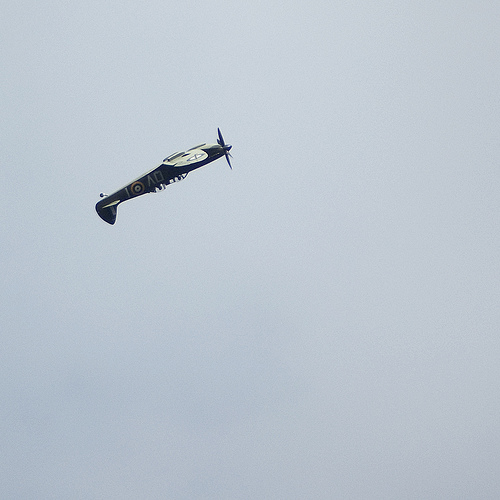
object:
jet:
[95, 126, 234, 225]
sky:
[2, 0, 500, 499]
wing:
[163, 149, 209, 167]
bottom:
[163, 149, 208, 167]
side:
[121, 164, 180, 201]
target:
[131, 182, 145, 196]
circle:
[135, 185, 140, 192]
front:
[215, 142, 232, 158]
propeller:
[216, 128, 233, 170]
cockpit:
[144, 172, 188, 193]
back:
[94, 192, 120, 225]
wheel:
[100, 193, 104, 198]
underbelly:
[126, 142, 220, 186]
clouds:
[0, 0, 499, 499]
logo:
[186, 154, 204, 161]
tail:
[95, 197, 121, 225]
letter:
[148, 175, 157, 187]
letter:
[154, 170, 164, 183]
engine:
[224, 143, 231, 152]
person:
[156, 184, 162, 190]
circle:
[130, 181, 145, 195]